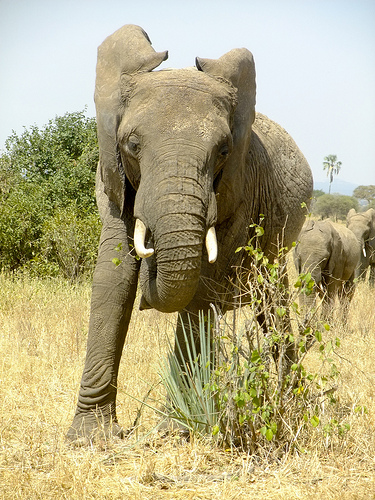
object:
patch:
[241, 219, 325, 321]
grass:
[321, 317, 375, 498]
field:
[0, 306, 375, 498]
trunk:
[359, 264, 370, 283]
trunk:
[232, 259, 251, 303]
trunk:
[304, 289, 328, 330]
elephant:
[295, 220, 361, 328]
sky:
[0, 1, 374, 189]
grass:
[334, 288, 375, 353]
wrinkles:
[253, 152, 295, 209]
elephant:
[63, 25, 314, 448]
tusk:
[205, 226, 219, 263]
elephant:
[344, 206, 374, 283]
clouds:
[17, 20, 75, 100]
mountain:
[315, 178, 375, 217]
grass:
[162, 452, 209, 500]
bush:
[0, 102, 96, 280]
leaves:
[28, 186, 51, 217]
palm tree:
[322, 152, 342, 193]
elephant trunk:
[131, 172, 218, 317]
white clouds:
[16, 34, 94, 87]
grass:
[158, 305, 244, 434]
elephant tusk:
[319, 282, 324, 291]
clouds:
[165, 0, 375, 46]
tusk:
[133, 218, 154, 258]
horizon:
[313, 184, 375, 194]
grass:
[1, 283, 65, 499]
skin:
[160, 73, 195, 126]